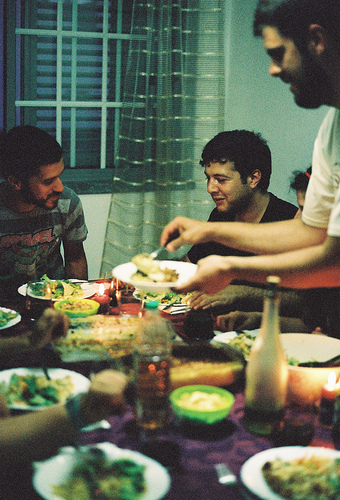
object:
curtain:
[98, 2, 225, 278]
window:
[6, 1, 196, 192]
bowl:
[169, 383, 235, 432]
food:
[177, 388, 228, 411]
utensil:
[147, 247, 165, 260]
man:
[181, 127, 302, 268]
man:
[0, 123, 89, 287]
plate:
[239, 443, 339, 498]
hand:
[160, 214, 208, 255]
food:
[133, 250, 177, 280]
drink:
[240, 286, 287, 432]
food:
[2, 367, 75, 404]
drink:
[133, 298, 171, 428]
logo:
[0, 227, 60, 280]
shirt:
[0, 184, 88, 284]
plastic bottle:
[132, 298, 172, 427]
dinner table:
[1, 278, 338, 498]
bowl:
[54, 298, 99, 315]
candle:
[88, 281, 112, 309]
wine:
[242, 381, 287, 437]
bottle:
[243, 275, 290, 437]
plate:
[112, 256, 206, 290]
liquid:
[141, 355, 173, 420]